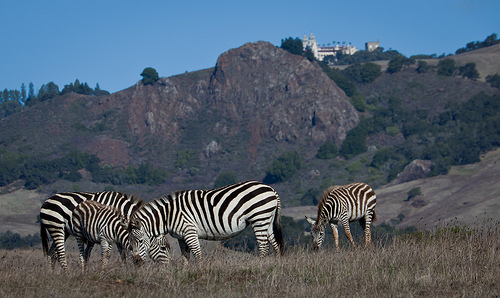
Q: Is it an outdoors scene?
A: Yes, it is outdoors.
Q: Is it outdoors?
A: Yes, it is outdoors.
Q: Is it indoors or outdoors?
A: It is outdoors.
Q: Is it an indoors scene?
A: No, it is outdoors.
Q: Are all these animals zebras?
A: Yes, all the animals are zebras.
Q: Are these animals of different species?
A: No, all the animals are zebras.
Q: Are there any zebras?
A: Yes, there is a zebra.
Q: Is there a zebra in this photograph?
A: Yes, there is a zebra.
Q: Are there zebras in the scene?
A: Yes, there is a zebra.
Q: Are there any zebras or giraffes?
A: Yes, there is a zebra.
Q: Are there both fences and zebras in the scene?
A: No, there is a zebra but no fences.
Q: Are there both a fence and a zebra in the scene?
A: No, there is a zebra but no fences.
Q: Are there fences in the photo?
A: No, there are no fences.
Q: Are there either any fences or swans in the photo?
A: No, there are no fences or swans.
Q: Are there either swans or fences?
A: No, there are no fences or swans.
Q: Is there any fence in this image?
A: No, there are no fences.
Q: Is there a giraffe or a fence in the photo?
A: No, there are no fences or giraffes.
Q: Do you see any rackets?
A: No, there are no rackets.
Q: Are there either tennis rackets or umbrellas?
A: No, there are no tennis rackets or umbrellas.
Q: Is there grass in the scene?
A: Yes, there is grass.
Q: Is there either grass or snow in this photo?
A: Yes, there is grass.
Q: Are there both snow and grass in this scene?
A: No, there is grass but no snow.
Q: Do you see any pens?
A: No, there are no pens.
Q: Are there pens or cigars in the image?
A: No, there are no pens or cigars.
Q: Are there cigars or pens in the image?
A: No, there are no pens or cigars.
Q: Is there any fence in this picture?
A: No, there are no fences.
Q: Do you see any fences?
A: No, there are no fences.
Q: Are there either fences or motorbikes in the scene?
A: No, there are no fences or motorbikes.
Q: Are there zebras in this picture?
A: Yes, there is a zebra.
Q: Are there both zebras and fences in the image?
A: No, there is a zebra but no fences.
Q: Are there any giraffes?
A: No, there are no giraffes.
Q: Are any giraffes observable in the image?
A: No, there are no giraffes.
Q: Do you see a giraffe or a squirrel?
A: No, there are no giraffes or squirrels.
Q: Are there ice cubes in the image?
A: No, there are no ice cubes.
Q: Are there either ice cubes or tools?
A: No, there are no ice cubes or tools.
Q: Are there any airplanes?
A: No, there are no airplanes.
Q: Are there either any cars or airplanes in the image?
A: No, there are no airplanes or cars.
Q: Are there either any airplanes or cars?
A: No, there are no airplanes or cars.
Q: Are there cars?
A: No, there are no cars.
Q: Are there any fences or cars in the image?
A: No, there are no cars or fences.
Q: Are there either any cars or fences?
A: No, there are no cars or fences.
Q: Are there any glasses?
A: No, there are no glasses.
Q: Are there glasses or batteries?
A: No, there are no glasses or batteries.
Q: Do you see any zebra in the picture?
A: Yes, there is a zebra.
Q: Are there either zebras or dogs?
A: Yes, there is a zebra.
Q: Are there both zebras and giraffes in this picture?
A: No, there is a zebra but no giraffes.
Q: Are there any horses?
A: No, there are no horses.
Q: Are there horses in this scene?
A: No, there are no horses.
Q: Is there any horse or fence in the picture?
A: No, there are no horses or fences.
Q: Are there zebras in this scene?
A: Yes, there is a zebra.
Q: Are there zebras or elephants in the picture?
A: Yes, there is a zebra.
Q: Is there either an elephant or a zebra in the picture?
A: Yes, there is a zebra.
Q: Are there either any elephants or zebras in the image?
A: Yes, there is a zebra.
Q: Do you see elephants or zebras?
A: Yes, there is a zebra.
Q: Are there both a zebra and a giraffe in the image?
A: No, there is a zebra but no giraffes.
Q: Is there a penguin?
A: No, there are no penguins.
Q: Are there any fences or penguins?
A: No, there are no penguins or fences.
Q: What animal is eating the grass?
A: The zebra is eating the grass.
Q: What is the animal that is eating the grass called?
A: The animal is a zebra.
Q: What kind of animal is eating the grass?
A: The animal is a zebra.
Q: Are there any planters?
A: No, there are no planters.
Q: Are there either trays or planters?
A: No, there are no planters or trays.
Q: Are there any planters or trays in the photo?
A: No, there are no planters or trays.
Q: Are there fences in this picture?
A: No, there are no fences.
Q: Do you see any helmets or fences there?
A: No, there are no fences or helmets.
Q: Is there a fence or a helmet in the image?
A: No, there are no fences or helmets.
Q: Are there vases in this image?
A: No, there are no vases.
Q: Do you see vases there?
A: No, there are no vases.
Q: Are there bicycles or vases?
A: No, there are no vases or bicycles.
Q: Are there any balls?
A: No, there are no balls.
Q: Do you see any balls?
A: No, there are no balls.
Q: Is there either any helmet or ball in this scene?
A: No, there are no balls or helmets.